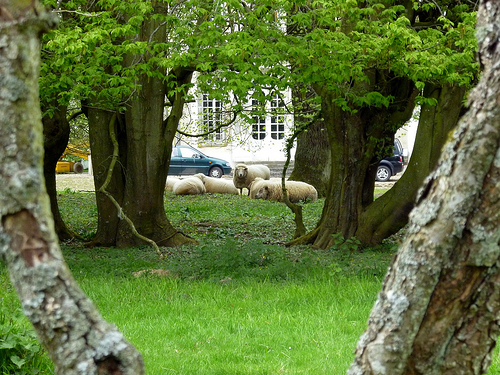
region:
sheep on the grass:
[141, 138, 352, 217]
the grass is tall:
[166, 279, 348, 333]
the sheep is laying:
[172, 175, 217, 195]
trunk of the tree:
[287, 180, 374, 258]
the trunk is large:
[75, 200, 190, 259]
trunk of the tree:
[328, 265, 478, 363]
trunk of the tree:
[4, 244, 112, 354]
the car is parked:
[161, 123, 238, 171]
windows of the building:
[163, 71, 295, 141]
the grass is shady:
[152, 220, 278, 291]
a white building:
[182, 42, 305, 169]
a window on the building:
[247, 76, 284, 129]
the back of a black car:
[354, 128, 405, 181]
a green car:
[165, 145, 237, 172]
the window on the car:
[181, 148, 194, 157]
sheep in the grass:
[168, 163, 303, 208]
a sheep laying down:
[254, 181, 321, 204]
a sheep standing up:
[227, 163, 262, 185]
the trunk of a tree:
[78, 21, 194, 251]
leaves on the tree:
[54, 10, 494, 86]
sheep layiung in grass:
[167, 161, 322, 210]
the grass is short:
[179, 292, 319, 337]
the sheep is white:
[165, 172, 216, 197]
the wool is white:
[271, 175, 325, 197]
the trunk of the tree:
[366, 208, 498, 358]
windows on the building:
[225, 79, 297, 136]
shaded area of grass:
[148, 215, 302, 273]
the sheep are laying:
[172, 139, 342, 196]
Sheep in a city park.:
[165, 161, 318, 206]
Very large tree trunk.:
[76, 1, 200, 252]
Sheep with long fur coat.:
[164, 162, 319, 206]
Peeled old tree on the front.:
[395, 140, 494, 370]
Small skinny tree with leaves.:
[277, 72, 317, 237]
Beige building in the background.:
[167, 7, 412, 179]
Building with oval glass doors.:
[245, 80, 290, 150]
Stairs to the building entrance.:
[221, 156, 304, 180]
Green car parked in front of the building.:
[170, 140, 237, 180]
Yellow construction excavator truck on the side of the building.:
[55, 135, 90, 175]